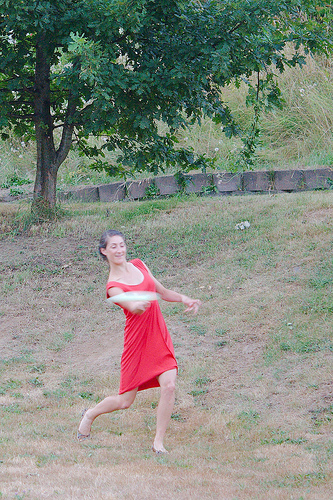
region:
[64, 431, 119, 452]
flat shoes on woman's foot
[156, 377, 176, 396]
crinkly knees on woman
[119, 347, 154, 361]
wrinkles in red dress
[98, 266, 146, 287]
woman's bare chest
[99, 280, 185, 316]
woman throwing white frisbee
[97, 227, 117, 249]
small amount of gray hair in woman's hair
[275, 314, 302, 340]
small green leaf on ground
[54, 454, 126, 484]
brown grass on the ground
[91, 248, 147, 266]
grin on woman's face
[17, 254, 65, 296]
patch of green grass in field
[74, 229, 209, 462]
Woman in red dress catching frisbee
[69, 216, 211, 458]
Woman in park catching a frisbee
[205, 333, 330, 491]
Grass that has not been watered in a while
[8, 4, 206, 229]
Tree with full foliage in a park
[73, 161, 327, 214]
Short stone wall in a park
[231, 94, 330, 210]
Tall grass behind a stone wall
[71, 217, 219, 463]
Woman having fun playing frisbee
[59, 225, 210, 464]
Woman playing barefoot in the park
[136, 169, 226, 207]
Weeds growing up a stone wall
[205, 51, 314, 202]
Low hanging branch on a tree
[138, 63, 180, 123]
part of some leaves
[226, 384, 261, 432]
part of some grass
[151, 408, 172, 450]
part of a leg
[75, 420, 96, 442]
part of a foot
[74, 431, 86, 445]
part of a shoe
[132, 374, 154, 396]
edge of the dress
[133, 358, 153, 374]
part of a dress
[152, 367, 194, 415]
part of a knee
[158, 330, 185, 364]
line on the dress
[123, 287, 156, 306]
part of a bird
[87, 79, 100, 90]
a green tree leaf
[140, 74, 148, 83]
a green tree leaf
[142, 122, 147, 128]
a green tree leaf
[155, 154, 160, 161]
a green tree leaf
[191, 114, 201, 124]
a green tree leaf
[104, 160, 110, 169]
a green tree leaf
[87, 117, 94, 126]
a green tree leaf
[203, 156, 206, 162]
a green tree leaf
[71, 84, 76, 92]
a green tree leaf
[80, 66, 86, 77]
a green tree leaf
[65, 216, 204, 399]
Woman is wearing a red dress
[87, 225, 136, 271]
Woman has dark colored hair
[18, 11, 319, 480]
Photo was taken in the daytime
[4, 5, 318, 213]
A tree is in the background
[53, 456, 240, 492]
Grass is dried up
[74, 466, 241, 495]
Grass is tan in color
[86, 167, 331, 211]
A formation of stones is in the background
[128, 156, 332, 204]
Stones are square shaped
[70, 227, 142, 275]
Woman has short hair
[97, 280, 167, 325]
Object in woman's hand is blurred